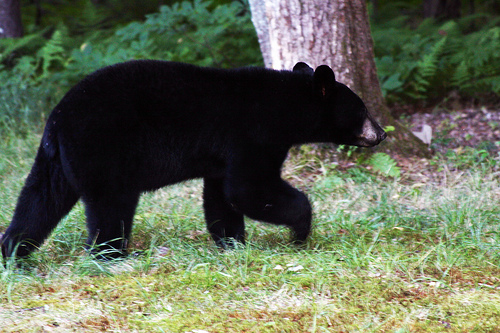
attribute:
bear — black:
[1, 58, 388, 258]